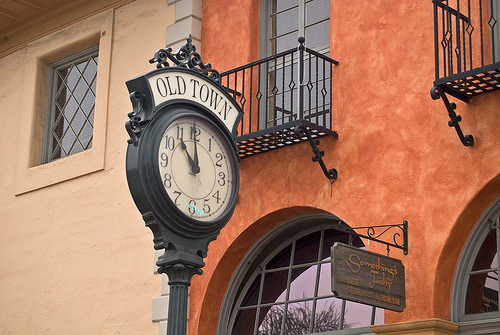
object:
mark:
[186, 201, 206, 215]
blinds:
[41, 44, 100, 165]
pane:
[68, 108, 89, 137]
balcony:
[429, 0, 499, 105]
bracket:
[429, 85, 475, 148]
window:
[463, 269, 500, 315]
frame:
[450, 197, 500, 322]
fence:
[220, 36, 336, 157]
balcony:
[215, 36, 338, 158]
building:
[188, 0, 500, 334]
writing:
[155, 75, 232, 121]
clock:
[126, 110, 239, 240]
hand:
[179, 136, 194, 167]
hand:
[191, 118, 199, 163]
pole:
[156, 247, 205, 334]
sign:
[329, 241, 405, 313]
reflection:
[257, 248, 384, 334]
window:
[291, 231, 321, 266]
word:
[155, 75, 186, 98]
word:
[190, 79, 233, 121]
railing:
[218, 45, 300, 76]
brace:
[338, 217, 408, 256]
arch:
[195, 204, 383, 333]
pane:
[62, 63, 83, 93]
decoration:
[147, 34, 222, 87]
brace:
[295, 123, 339, 182]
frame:
[124, 100, 240, 257]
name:
[340, 251, 400, 293]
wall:
[1, 1, 176, 334]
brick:
[173, 1, 201, 20]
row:
[151, 1, 204, 331]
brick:
[151, 295, 190, 320]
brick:
[165, 17, 206, 47]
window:
[303, 1, 330, 29]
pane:
[258, 267, 291, 308]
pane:
[283, 296, 317, 334]